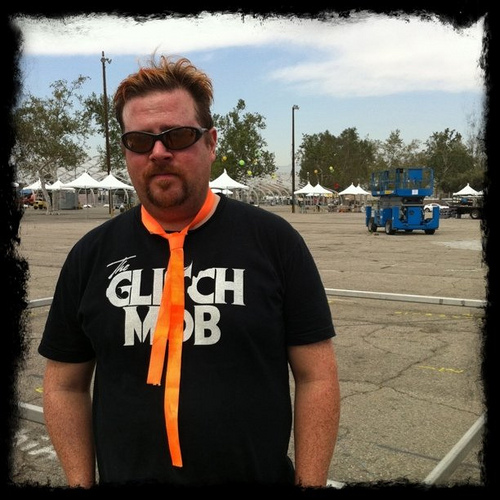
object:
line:
[329, 287, 487, 309]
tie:
[145, 248, 184, 469]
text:
[104, 259, 245, 347]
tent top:
[209, 168, 250, 191]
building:
[6, 155, 299, 215]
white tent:
[293, 181, 314, 195]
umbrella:
[305, 181, 333, 197]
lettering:
[106, 255, 245, 346]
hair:
[112, 46, 215, 150]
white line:
[418, 415, 488, 485]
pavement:
[15, 199, 485, 484]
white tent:
[453, 182, 478, 195]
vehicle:
[365, 167, 439, 235]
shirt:
[34, 189, 336, 490]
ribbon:
[138, 189, 219, 465]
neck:
[146, 210, 209, 233]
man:
[37, 44, 342, 484]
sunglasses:
[120, 125, 208, 153]